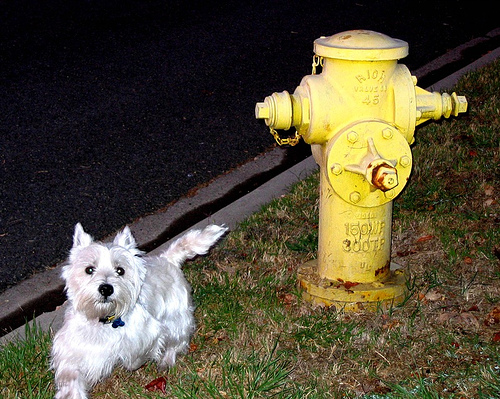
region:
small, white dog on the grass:
[50, 220, 229, 397]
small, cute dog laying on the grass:
[53, 220, 228, 397]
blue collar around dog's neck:
[100, 314, 125, 328]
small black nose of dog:
[97, 285, 112, 295]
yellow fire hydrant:
[254, 27, 468, 303]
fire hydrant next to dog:
[253, 29, 468, 309]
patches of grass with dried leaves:
[0, 57, 498, 397]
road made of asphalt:
[0, 0, 499, 328]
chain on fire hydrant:
[267, 52, 324, 147]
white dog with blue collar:
[51, 220, 230, 397]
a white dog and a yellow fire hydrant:
[43, 27, 468, 397]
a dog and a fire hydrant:
[50, 28, 469, 398]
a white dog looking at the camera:
[48, 222, 235, 397]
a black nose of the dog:
[98, 282, 114, 299]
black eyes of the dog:
[81, 260, 126, 275]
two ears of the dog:
[71, 220, 136, 250]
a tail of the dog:
[163, 223, 227, 261]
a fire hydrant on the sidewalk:
[253, 28, 468, 322]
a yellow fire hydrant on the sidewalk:
[253, 27, 467, 320]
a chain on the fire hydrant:
[266, 126, 299, 146]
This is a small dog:
[50, 203, 272, 390]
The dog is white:
[76, 223, 241, 377]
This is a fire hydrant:
[289, 34, 486, 341]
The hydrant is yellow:
[262, 37, 497, 378]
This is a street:
[55, 90, 221, 125]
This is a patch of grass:
[238, 223, 377, 376]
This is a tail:
[150, 204, 227, 271]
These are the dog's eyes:
[61, 250, 141, 277]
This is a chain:
[268, 80, 297, 178]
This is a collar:
[93, 318, 132, 330]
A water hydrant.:
[250, 28, 476, 304]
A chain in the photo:
[260, 125, 305, 142]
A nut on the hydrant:
[370, 150, 395, 190]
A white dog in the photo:
[37, 207, 227, 396]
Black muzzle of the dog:
[98, 281, 115, 301]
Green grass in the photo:
[212, 287, 244, 335]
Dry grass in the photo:
[315, 355, 382, 387]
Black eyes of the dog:
[81, 262, 128, 281]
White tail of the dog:
[170, 219, 229, 261]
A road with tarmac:
[28, 162, 143, 202]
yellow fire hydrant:
[248, 23, 476, 318]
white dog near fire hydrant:
[51, 212, 236, 397]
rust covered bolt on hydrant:
[369, 155, 408, 200]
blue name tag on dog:
[110, 314, 130, 330]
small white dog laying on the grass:
[5, 199, 497, 397]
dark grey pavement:
[1, 0, 497, 320]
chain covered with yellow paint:
[263, 124, 313, 151]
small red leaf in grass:
[134, 368, 181, 397]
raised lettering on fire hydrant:
[336, 210, 404, 257]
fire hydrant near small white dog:
[1, 5, 498, 393]